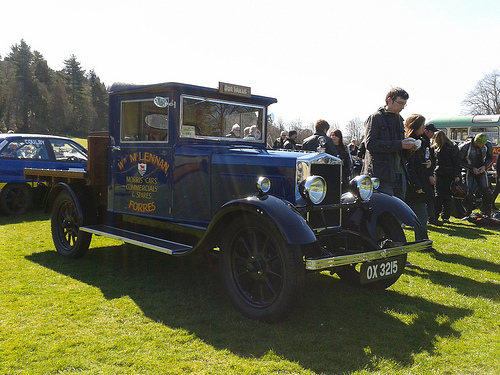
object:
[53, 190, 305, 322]
dark rims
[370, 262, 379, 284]
number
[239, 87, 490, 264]
crowd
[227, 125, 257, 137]
people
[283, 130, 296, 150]
people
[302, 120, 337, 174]
people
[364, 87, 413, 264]
people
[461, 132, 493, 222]
people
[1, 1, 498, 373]
outside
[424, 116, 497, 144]
bus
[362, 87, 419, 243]
man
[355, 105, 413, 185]
jacket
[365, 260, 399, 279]
6 letter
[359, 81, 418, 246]
person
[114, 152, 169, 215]
sign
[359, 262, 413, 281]
license plate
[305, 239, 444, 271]
bumper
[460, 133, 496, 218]
man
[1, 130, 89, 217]
car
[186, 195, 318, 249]
fender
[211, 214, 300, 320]
wheel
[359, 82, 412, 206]
person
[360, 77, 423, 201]
man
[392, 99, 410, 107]
glasses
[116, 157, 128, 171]
word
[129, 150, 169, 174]
word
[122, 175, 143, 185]
word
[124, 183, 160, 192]
word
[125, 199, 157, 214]
word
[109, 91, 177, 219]
door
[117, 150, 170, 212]
text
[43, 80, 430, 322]
car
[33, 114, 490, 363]
grass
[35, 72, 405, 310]
truck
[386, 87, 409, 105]
hair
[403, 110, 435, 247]
woman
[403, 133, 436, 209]
wearing jacket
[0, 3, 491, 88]
sky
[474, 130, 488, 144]
hat